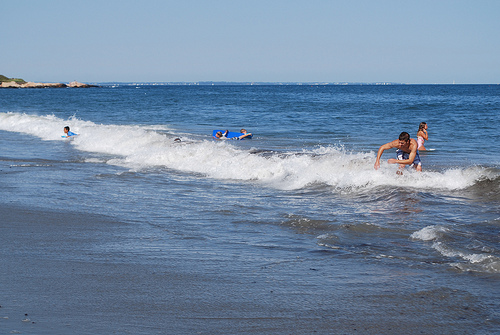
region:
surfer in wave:
[53, 124, 88, 148]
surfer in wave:
[376, 130, 426, 182]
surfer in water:
[205, 123, 235, 147]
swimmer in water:
[416, 122, 437, 149]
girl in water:
[413, 122, 431, 156]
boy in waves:
[377, 133, 419, 175]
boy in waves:
[56, 125, 76, 140]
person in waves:
[213, 125, 231, 148]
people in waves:
[371, 119, 441, 179]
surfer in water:
[418, 118, 445, 155]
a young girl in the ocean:
[416, 114, 432, 154]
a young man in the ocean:
[378, 126, 424, 179]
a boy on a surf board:
[41, 116, 84, 150]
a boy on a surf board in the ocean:
[204, 119, 262, 158]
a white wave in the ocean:
[114, 135, 477, 197]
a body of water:
[46, 73, 468, 113]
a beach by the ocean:
[1, 217, 464, 315]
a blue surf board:
[214, 128, 253, 139]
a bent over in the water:
[372, 138, 424, 186]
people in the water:
[26, 110, 450, 208]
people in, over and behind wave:
[12, 17, 488, 322]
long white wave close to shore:
[2, 101, 494, 287]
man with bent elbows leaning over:
[367, 127, 418, 177]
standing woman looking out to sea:
[415, 115, 440, 155]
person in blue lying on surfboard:
[57, 120, 77, 140]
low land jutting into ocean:
[0, 70, 95, 90]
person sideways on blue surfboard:
[210, 125, 255, 140]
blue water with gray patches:
[2, 90, 492, 330]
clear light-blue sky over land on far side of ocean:
[0, 5, 495, 85]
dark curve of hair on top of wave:
[170, 135, 185, 150]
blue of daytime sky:
[1, 0, 497, 80]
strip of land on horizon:
[99, 80, 405, 86]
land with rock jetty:
[3, 75, 96, 88]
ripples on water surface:
[3, 85, 497, 119]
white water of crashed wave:
[1, 111, 496, 191]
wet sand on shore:
[2, 207, 497, 332]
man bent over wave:
[374, 131, 423, 176]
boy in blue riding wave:
[59, 125, 76, 138]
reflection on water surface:
[348, 187, 475, 222]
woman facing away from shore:
[415, 120, 430, 151]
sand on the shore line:
[25, 269, 124, 307]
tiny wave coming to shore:
[407, 227, 468, 262]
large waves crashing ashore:
[114, 115, 367, 193]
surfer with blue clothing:
[51, 126, 89, 135]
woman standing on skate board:
[415, 113, 437, 151]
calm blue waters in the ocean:
[253, 86, 362, 116]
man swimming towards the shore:
[209, 124, 262, 148]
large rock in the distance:
[5, 69, 99, 94]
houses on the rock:
[68, 70, 114, 103]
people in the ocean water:
[62, 109, 454, 201]